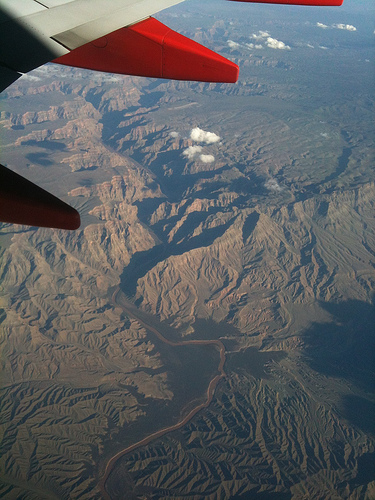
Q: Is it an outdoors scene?
A: Yes, it is outdoors.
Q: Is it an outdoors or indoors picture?
A: It is outdoors.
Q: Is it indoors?
A: No, it is outdoors.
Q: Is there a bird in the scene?
A: No, there are no birds.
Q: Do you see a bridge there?
A: No, there are no bridges.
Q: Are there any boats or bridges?
A: No, there are no bridges or boats.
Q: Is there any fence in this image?
A: No, there are no fences.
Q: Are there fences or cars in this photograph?
A: No, there are no fences or cars.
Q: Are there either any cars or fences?
A: No, there are no fences or cars.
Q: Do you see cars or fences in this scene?
A: No, there are no fences or cars.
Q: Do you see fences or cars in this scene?
A: No, there are no fences or cars.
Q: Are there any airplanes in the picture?
A: Yes, there is an airplane.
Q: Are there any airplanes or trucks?
A: Yes, there is an airplane.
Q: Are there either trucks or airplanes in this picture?
A: Yes, there is an airplane.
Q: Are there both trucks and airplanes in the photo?
A: No, there is an airplane but no trucks.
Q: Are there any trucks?
A: No, there are no trucks.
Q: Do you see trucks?
A: No, there are no trucks.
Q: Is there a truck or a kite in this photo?
A: No, there are no trucks or kites.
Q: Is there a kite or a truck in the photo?
A: No, there are no trucks or kites.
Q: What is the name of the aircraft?
A: The aircraft is an airplane.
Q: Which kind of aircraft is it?
A: The aircraft is an airplane.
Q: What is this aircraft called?
A: That is an airplane.